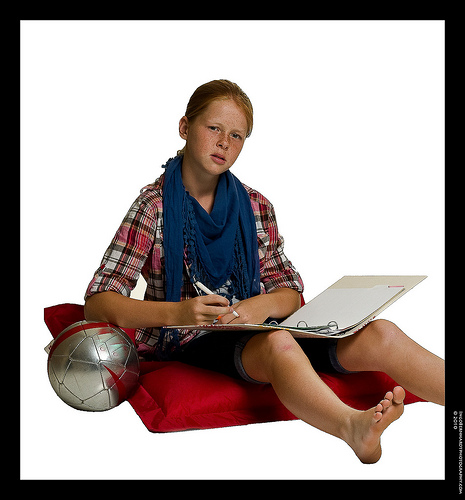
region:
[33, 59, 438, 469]
a girl on a red large pillow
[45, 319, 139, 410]
a red and silver ball next to the pillow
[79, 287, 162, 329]
an arm resting on a ball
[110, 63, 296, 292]
a girl wearing a blue scarf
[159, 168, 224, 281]
a blue scarf the girl is wearing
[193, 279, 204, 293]
a top of the pen the kid is using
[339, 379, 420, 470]
a foot the kid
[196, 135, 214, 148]
frickles on the face of the kid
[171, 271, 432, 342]
a note book the kid is writing on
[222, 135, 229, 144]
the freckles on the nose of the kid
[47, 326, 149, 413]
A shining silver soccer ball.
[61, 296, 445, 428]
A big red floor pillow.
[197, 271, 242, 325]
A hand holding a white pen.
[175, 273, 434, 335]
White three pronged notebook with paper.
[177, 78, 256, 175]
A girl with long red hair.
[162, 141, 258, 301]
A blue sweater around a girl's neck.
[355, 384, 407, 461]
Bare foot stinky toe toes.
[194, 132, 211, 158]
Freckles on a girl's face.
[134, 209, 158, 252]
Red and black plaid pattern on a shirt.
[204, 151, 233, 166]
A girls two pink lips.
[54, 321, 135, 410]
silver and red soccer ball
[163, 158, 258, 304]
blue scarf on neck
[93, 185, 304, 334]
red and white shirt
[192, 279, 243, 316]
white pen in hand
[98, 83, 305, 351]
girl wearing plaid shirt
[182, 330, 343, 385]
dark blue denim shorts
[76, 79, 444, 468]
girl sitting on red mat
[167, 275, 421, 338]
ivory binder file folder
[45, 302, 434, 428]
red cushioned floor mat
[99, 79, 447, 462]
girl not wearing shoes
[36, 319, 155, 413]
silver colored sports ball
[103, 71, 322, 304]
young lady with ginger colored hair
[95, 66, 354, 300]
teenage girl with red hair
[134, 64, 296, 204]
teenage girl studying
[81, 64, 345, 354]
teenage girl wearing plaid shirt with blue scarf around neck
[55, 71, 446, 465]
young lady sitting on floor pillow studying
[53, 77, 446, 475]
barefoot girl studying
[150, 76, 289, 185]
red haired girl with freckles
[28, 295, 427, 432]
red floor pillow for sitting on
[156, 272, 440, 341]
Three ring notebook with tabbed divider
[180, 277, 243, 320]
hand holding a white pen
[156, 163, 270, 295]
dark blue scarf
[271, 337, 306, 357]
red scar on a knee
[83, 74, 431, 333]
red haired girl writing in notebook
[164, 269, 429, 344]
three ring binder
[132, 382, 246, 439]
corner of a red pillow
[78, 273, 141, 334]
elbow resting on a ball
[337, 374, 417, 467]
foot resting on the floor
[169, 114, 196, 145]
girl's right ear